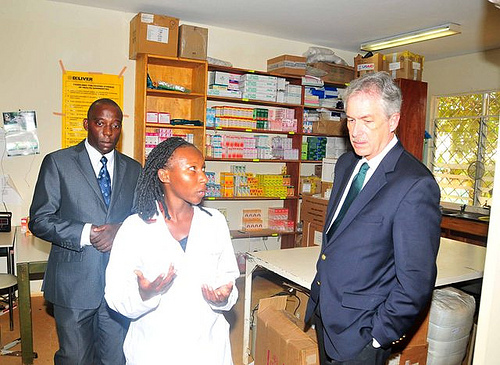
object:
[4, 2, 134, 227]
wall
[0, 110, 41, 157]
poster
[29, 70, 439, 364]
three people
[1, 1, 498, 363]
room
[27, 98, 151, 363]
man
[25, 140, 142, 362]
suit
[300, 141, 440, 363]
suit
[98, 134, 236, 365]
people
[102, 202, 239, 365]
coat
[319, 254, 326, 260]
button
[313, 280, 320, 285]
button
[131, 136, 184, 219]
dark hair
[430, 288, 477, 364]
bundle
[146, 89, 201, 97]
shelf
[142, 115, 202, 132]
shelf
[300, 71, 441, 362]
man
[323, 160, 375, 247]
blue tie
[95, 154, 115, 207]
blue tie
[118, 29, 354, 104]
ceiling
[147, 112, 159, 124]
boxes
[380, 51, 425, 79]
boxes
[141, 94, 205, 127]
shelf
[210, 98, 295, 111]
shelf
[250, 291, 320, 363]
box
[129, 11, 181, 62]
box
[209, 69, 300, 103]
objects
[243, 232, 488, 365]
table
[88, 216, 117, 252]
hands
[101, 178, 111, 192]
spots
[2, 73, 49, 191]
wall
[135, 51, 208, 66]
shelf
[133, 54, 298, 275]
bookshelves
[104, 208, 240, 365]
white shirt